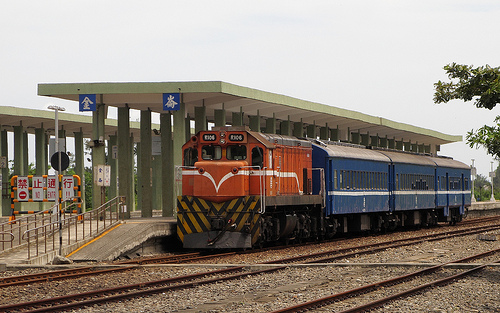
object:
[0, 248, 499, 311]
foreground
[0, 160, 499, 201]
background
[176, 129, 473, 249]
train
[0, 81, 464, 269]
station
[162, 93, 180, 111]
sign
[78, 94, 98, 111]
sign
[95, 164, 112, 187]
sign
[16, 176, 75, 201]
sign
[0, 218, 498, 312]
track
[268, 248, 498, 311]
track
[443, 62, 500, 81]
branch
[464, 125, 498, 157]
branch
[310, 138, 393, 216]
car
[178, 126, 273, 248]
engine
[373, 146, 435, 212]
car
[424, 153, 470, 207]
car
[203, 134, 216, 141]
sign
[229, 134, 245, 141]
sign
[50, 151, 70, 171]
traffic sign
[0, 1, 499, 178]
sky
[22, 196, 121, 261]
railing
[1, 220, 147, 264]
ramp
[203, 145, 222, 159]
window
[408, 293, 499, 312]
gravel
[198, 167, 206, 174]
headlight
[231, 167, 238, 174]
headlight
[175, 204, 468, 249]
bottom